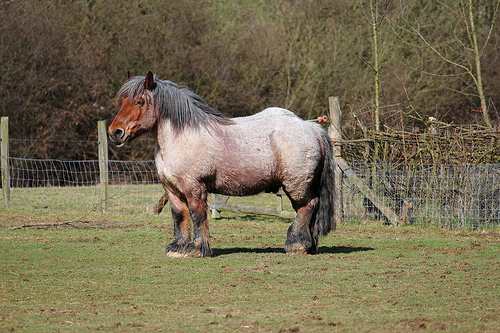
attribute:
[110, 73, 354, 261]
horse — brown, black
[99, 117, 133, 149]
snout — big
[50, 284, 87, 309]
grass — green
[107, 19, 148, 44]
tree — brown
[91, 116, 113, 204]
post — wooden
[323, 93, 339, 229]
post — wooden